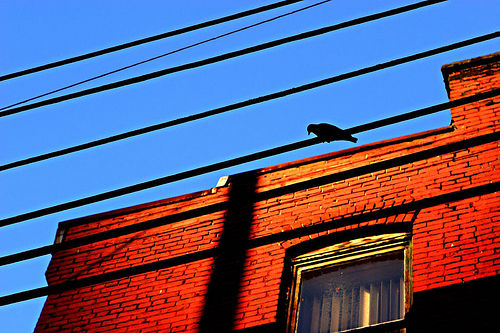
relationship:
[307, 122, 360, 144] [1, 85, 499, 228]
bird on wire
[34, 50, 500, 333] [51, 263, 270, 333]
building made of bricks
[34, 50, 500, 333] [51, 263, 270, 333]
building with bricks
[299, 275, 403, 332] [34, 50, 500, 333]
blinds on building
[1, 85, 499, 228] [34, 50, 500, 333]
wire near building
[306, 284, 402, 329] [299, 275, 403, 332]
blinds in blinds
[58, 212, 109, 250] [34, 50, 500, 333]
corner of building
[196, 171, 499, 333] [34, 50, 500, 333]
shadow on building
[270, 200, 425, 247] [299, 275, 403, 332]
arch above blinds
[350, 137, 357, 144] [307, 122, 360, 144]
tail of bird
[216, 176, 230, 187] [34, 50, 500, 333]
white mark on building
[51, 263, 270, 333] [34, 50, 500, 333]
bricks in building